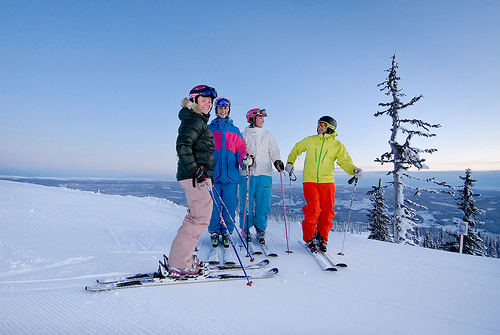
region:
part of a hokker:
[236, 248, 253, 276]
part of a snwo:
[384, 273, 410, 303]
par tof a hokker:
[235, 260, 245, 290]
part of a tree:
[382, 182, 395, 239]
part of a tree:
[370, 216, 396, 263]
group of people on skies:
[167, 78, 357, 283]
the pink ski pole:
[275, 170, 294, 254]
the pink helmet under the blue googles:
[183, 82, 218, 110]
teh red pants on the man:
[303, 181, 331, 248]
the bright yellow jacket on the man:
[280, 127, 362, 189]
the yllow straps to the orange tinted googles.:
[313, 119, 336, 133]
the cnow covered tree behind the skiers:
[363, 48, 433, 253]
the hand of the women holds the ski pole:
[184, 165, 211, 187]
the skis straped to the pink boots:
[78, 249, 281, 301]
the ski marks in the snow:
[6, 243, 82, 312]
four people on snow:
[165, 28, 403, 286]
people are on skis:
[71, 84, 383, 279]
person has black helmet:
[318, 115, 336, 145]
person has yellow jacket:
[291, 130, 362, 187]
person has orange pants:
[298, 184, 359, 241]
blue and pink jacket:
[207, 111, 259, 192]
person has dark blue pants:
[210, 183, 248, 255]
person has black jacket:
[170, 98, 215, 190]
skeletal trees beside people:
[378, 63, 498, 295]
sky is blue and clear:
[227, 3, 325, 103]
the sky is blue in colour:
[96, 38, 220, 87]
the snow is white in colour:
[22, 192, 102, 279]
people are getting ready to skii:
[88, 53, 358, 307]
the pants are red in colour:
[303, 172, 339, 246]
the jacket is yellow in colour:
[291, 133, 360, 193]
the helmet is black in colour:
[314, 116, 336, 126]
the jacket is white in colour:
[249, 124, 279, 175]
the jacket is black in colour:
[168, 116, 215, 177]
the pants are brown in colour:
[176, 164, 215, 282]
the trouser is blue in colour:
[245, 173, 273, 229]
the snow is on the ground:
[36, 183, 101, 255]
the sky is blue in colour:
[86, 20, 301, 77]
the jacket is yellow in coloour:
[296, 135, 352, 179]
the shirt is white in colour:
[239, 128, 284, 173]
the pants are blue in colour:
[246, 177, 271, 224]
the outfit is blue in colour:
[216, 113, 237, 241]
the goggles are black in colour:
[183, 84, 222, 103]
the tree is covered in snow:
[373, 49, 415, 237]